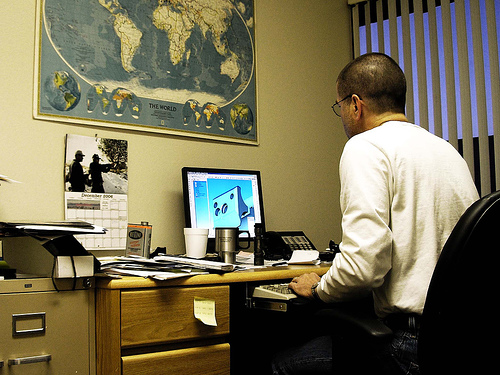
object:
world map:
[34, 2, 260, 142]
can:
[127, 219, 152, 258]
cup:
[213, 222, 236, 265]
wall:
[2, 0, 357, 256]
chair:
[415, 188, 499, 374]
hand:
[291, 272, 319, 298]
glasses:
[322, 93, 353, 117]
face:
[335, 80, 355, 137]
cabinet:
[1, 277, 98, 374]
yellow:
[191, 294, 221, 329]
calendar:
[61, 130, 130, 253]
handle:
[236, 230, 251, 250]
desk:
[95, 263, 334, 374]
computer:
[181, 166, 270, 239]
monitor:
[180, 162, 267, 239]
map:
[33, 0, 260, 146]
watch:
[311, 280, 324, 304]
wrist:
[309, 275, 334, 300]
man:
[257, 50, 482, 375]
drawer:
[119, 286, 231, 346]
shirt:
[314, 120, 481, 317]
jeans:
[246, 313, 421, 373]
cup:
[183, 226, 209, 258]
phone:
[268, 229, 319, 261]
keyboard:
[252, 281, 320, 300]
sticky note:
[190, 296, 226, 326]